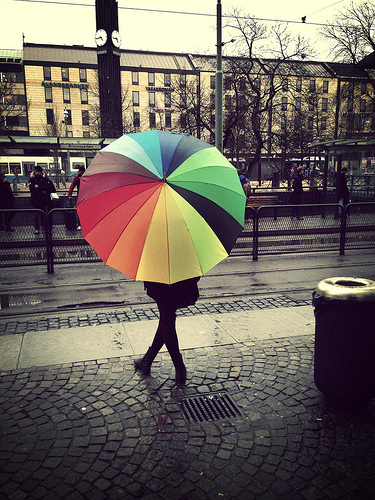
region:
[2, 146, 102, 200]
the bus is white and blue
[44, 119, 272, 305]
umbrella is multi colored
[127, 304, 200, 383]
woman has legs crossed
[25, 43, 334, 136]
the building is brown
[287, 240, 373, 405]
trash can behind woman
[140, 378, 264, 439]
drain in ground behind woman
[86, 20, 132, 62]
clock on the building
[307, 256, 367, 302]
top of trash can is silver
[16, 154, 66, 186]
person is wearing a hat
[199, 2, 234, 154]
the pole is gray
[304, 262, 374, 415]
trash can sitting on sidewalk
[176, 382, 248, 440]
metal grate in sidewalk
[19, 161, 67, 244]
man in black coat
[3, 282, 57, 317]
puddle of rain water on street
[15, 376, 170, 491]
decorative tile used for sidewalk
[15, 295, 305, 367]
cement walkway on sidewalk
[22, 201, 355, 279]
metal fencing running between sidewalk and street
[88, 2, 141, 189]
clock tower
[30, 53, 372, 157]
multi level of windows in building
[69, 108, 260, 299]
large colorful umbrella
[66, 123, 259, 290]
a large colorful umbrella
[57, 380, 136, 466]
wet bricks in the sidewalk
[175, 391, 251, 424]
a metal storm drain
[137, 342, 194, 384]
black boots on feet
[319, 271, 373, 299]
a silver top on the trash can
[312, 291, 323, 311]
a black plastic bag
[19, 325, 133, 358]
gray concrete slab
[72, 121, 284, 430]
a person holding a large umbrella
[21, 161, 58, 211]
a man holding a white bag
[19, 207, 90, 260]
a black metal gate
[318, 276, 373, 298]
a black trashcan on the brick walkway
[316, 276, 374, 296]
silver top on the black trashcan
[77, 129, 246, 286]
an opened multi-colored umbrella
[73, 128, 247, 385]
a woman holding an opened umbrella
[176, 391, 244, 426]
a water drain in a bricked walkway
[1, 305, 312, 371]
a concrete walkway in front of the woman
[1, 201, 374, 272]
a black metal wire fence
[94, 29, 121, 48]
two clocks on a black tower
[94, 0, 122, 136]
a clock tower behind the port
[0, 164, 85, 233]
three people standing under the port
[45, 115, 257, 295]
umbrella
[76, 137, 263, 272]
colorful umbrella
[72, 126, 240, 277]
colorful umbrella that is open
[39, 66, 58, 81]
window in tan building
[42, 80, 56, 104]
window in tan building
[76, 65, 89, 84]
window in tan building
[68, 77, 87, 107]
small black window in tan building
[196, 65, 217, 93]
black window in tan building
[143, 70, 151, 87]
black window in tan building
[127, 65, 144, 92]
black window in tan building